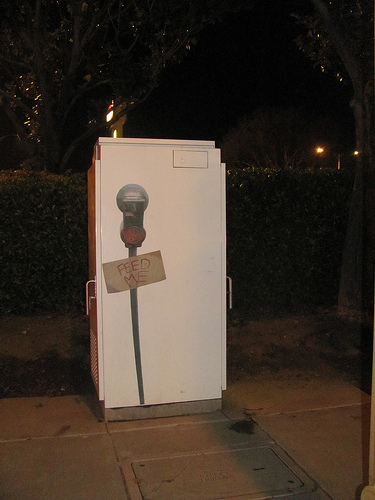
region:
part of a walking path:
[304, 411, 344, 446]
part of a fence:
[261, 196, 303, 244]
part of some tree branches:
[90, 88, 135, 124]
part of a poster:
[115, 260, 155, 282]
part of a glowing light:
[314, 143, 334, 163]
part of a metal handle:
[226, 277, 236, 308]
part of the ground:
[269, 325, 322, 365]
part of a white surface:
[183, 215, 216, 271]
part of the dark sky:
[241, 46, 279, 86]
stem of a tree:
[353, 195, 370, 250]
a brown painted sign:
[101, 247, 166, 295]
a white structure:
[85, 136, 229, 410]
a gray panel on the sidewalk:
[122, 438, 317, 498]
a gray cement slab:
[0, 430, 129, 498]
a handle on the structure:
[83, 276, 97, 315]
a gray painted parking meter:
[114, 180, 149, 249]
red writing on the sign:
[115, 257, 153, 290]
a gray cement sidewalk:
[0, 372, 371, 498]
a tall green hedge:
[0, 165, 369, 319]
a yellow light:
[310, 143, 326, 156]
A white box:
[60, 111, 282, 421]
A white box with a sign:
[50, 125, 229, 404]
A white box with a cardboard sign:
[77, 181, 186, 387]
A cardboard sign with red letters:
[96, 256, 168, 304]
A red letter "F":
[112, 261, 126, 279]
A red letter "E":
[136, 268, 149, 285]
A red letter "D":
[135, 255, 153, 270]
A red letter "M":
[120, 274, 139, 289]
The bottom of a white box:
[62, 378, 243, 427]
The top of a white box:
[57, 126, 241, 190]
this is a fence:
[242, 170, 304, 309]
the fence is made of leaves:
[250, 215, 306, 281]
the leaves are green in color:
[242, 223, 310, 294]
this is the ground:
[53, 426, 167, 497]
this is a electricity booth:
[168, 225, 224, 388]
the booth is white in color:
[182, 246, 201, 335]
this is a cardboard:
[103, 249, 164, 292]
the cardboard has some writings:
[113, 257, 155, 290]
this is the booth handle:
[84, 275, 95, 325]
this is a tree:
[35, 1, 75, 166]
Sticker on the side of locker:
[70, 120, 235, 373]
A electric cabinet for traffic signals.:
[49, 147, 235, 407]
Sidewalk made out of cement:
[278, 400, 315, 440]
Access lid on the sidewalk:
[98, 435, 235, 482]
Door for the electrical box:
[64, 150, 125, 379]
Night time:
[54, 23, 285, 248]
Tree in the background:
[29, 28, 110, 153]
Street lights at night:
[303, 113, 350, 185]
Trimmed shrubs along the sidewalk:
[246, 141, 369, 333]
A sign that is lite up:
[54, 88, 187, 152]